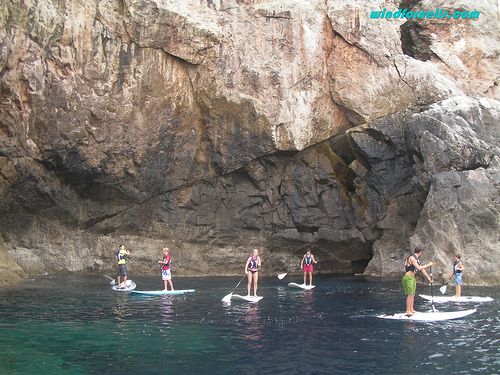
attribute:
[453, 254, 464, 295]
person — standing up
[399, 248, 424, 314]
person — standing up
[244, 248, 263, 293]
person — standing up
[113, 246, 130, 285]
person — standing up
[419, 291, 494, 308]
paddle board — white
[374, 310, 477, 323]
paddle board — white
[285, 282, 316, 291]
paddle board — white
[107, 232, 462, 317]
people — grouped, standing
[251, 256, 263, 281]
swimsuit — purple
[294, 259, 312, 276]
shorts — red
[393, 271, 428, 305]
shorts — green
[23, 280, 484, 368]
water — green, blue-green, blue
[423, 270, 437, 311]
paddle — black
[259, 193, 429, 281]
rock — black, light brown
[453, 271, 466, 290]
shorts — blue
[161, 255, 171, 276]
shirt — red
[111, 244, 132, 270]
shirt — yellow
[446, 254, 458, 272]
jacket — blue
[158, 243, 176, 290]
person — standing up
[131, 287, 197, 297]
paddle board — blue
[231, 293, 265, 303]
paddle board — white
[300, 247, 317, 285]
person — standing up